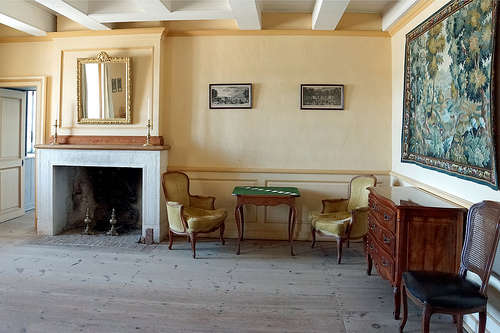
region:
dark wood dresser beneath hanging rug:
[360, 175, 470, 315]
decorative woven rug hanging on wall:
[395, 0, 495, 190]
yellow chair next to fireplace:
[155, 160, 225, 260]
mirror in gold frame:
[65, 45, 130, 125]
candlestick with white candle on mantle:
[140, 90, 155, 145]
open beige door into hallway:
[0, 70, 40, 230]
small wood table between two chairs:
[230, 172, 305, 242]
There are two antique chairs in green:
[162, 160, 374, 259]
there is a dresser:
[361, 175, 459, 317]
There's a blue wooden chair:
[403, 202, 496, 332]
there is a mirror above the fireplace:
[77, 43, 140, 130]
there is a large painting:
[388, 3, 498, 192]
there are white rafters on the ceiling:
[1, 0, 418, 37]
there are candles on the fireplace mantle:
[45, 93, 162, 145]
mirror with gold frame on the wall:
[61, 50, 141, 130]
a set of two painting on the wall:
[187, 71, 343, 111]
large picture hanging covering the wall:
[396, 4, 498, 181]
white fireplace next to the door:
[27, 140, 174, 256]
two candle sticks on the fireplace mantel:
[39, 117, 175, 146]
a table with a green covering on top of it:
[222, 175, 312, 260]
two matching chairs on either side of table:
[162, 160, 376, 262]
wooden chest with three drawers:
[361, 170, 471, 303]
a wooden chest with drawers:
[358, 176, 467, 318]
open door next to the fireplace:
[0, 75, 45, 231]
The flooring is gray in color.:
[94, 283, 291, 330]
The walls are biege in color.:
[185, 116, 309, 165]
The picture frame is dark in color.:
[207, 79, 257, 110]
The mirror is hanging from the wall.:
[71, 51, 136, 123]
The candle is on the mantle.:
[142, 97, 152, 148]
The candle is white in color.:
[146, 89, 151, 121]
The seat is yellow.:
[160, 168, 231, 260]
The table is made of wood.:
[233, 178, 307, 260]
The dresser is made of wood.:
[364, 184, 464, 304]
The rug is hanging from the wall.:
[401, 0, 498, 188]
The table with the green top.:
[230, 184, 299, 254]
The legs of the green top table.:
[235, 207, 297, 255]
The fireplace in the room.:
[33, 142, 163, 244]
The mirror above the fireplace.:
[73, 52, 131, 127]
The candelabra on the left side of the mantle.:
[52, 103, 58, 144]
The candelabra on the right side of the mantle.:
[145, 99, 152, 145]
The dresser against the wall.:
[367, 182, 466, 318]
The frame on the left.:
[208, 85, 250, 107]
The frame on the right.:
[302, 80, 346, 112]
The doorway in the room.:
[3, 77, 37, 234]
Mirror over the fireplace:
[73, 54, 133, 124]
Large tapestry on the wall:
[401, 1, 498, 188]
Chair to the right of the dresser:
[396, 197, 498, 329]